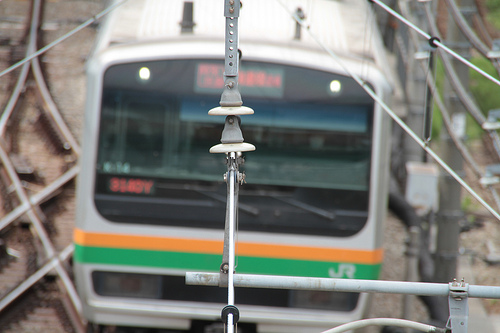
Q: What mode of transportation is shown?
A: A train.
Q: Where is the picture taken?
A: A railway.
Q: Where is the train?
A: On the tracks.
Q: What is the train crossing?
A: A bridge.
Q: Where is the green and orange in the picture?
A: The train's front.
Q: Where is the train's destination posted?
A: The train's front.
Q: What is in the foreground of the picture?
A: Pole.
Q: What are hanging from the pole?
A: Bells.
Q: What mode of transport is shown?
A: A train.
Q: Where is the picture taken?
A: A railway.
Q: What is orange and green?
A: A train.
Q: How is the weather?
A: Clear.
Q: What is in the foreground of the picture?
A: A pole with bells.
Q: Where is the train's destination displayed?
A: The train front.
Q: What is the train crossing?
A: A bridge.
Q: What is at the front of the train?
A: A windshield.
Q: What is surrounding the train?
A: Electrical wires.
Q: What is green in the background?
A: Grass.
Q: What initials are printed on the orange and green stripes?
A: JR.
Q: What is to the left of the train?
A: Tracks.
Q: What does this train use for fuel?
A: Electricity.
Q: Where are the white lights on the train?
A: Windshield.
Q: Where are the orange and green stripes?
A: On train.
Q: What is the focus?
A: Train.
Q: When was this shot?
A: Daytime.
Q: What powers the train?
A: Electricity.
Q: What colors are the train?
A: Green, orange, and grey.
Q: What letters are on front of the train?
A: JR.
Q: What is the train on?
A: Rail.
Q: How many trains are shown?
A: 1.